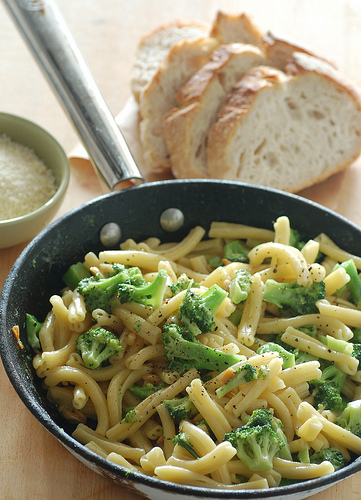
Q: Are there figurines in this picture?
A: No, there are no figurines.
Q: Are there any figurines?
A: No, there are no figurines.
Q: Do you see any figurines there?
A: No, there are no figurines.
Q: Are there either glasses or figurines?
A: No, there are no figurines or glasses.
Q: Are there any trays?
A: No, there are no trays.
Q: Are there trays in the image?
A: No, there are no trays.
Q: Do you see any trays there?
A: No, there are no trays.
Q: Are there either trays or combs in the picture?
A: No, there are no trays or combs.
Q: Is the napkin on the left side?
A: Yes, the napkin is on the left of the image.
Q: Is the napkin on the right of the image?
A: No, the napkin is on the left of the image.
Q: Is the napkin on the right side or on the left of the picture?
A: The napkin is on the left of the image.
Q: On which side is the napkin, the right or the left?
A: The napkin is on the left of the image.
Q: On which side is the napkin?
A: The napkin is on the left of the image.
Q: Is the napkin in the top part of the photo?
A: Yes, the napkin is in the top of the image.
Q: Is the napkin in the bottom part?
A: No, the napkin is in the top of the image.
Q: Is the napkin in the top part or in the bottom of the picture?
A: The napkin is in the top of the image.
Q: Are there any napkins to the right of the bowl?
A: Yes, there is a napkin to the right of the bowl.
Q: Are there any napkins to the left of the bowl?
A: No, the napkin is to the right of the bowl.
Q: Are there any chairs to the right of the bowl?
A: No, there is a napkin to the right of the bowl.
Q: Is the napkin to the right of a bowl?
A: Yes, the napkin is to the right of a bowl.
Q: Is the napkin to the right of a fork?
A: No, the napkin is to the right of a bowl.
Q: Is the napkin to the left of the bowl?
A: No, the napkin is to the right of the bowl.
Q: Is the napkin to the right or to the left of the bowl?
A: The napkin is to the right of the bowl.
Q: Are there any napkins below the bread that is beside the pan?
A: Yes, there is a napkin below the bread.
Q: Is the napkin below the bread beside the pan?
A: Yes, the napkin is below the bread.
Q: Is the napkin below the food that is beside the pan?
A: Yes, the napkin is below the bread.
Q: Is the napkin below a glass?
A: No, the napkin is below the bread.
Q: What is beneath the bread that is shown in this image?
A: The napkin is beneath the bread.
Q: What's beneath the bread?
A: The napkin is beneath the bread.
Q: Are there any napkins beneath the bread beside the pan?
A: Yes, there is a napkin beneath the bread.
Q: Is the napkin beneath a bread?
A: Yes, the napkin is beneath a bread.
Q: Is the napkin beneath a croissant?
A: No, the napkin is beneath a bread.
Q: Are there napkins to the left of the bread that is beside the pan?
A: Yes, there is a napkin to the left of the bread.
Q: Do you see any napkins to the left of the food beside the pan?
A: Yes, there is a napkin to the left of the bread.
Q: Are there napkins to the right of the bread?
A: No, the napkin is to the left of the bread.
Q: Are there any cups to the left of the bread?
A: No, there is a napkin to the left of the bread.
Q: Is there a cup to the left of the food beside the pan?
A: No, there is a napkin to the left of the bread.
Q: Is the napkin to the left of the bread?
A: Yes, the napkin is to the left of the bread.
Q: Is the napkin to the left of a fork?
A: No, the napkin is to the left of the bread.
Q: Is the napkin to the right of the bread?
A: No, the napkin is to the left of the bread.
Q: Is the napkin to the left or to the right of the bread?
A: The napkin is to the left of the bread.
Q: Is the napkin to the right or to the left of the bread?
A: The napkin is to the left of the bread.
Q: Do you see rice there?
A: Yes, there is rice.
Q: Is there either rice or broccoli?
A: Yes, there is rice.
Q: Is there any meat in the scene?
A: No, there is no meat.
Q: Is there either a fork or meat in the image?
A: No, there are no meat or forks.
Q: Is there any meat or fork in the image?
A: No, there are no meat or forks.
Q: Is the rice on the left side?
A: Yes, the rice is on the left of the image.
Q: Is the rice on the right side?
A: No, the rice is on the left of the image.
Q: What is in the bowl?
A: The rice is in the bowl.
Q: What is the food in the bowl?
A: The food is rice.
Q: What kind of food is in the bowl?
A: The food is rice.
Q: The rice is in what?
A: The rice is in the bowl.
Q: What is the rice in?
A: The rice is in the bowl.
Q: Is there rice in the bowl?
A: Yes, there is rice in the bowl.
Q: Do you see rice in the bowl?
A: Yes, there is rice in the bowl.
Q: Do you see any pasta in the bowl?
A: No, there is rice in the bowl.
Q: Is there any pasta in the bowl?
A: No, there is rice in the bowl.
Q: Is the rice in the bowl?
A: Yes, the rice is in the bowl.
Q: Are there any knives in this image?
A: No, there are no knives.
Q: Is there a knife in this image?
A: No, there are no knives.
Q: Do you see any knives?
A: No, there are no knives.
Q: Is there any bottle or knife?
A: No, there are no knives or bottles.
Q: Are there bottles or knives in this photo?
A: No, there are no knives or bottles.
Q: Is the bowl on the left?
A: Yes, the bowl is on the left of the image.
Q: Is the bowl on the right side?
A: No, the bowl is on the left of the image.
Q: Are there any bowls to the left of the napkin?
A: Yes, there is a bowl to the left of the napkin.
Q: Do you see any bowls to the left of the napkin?
A: Yes, there is a bowl to the left of the napkin.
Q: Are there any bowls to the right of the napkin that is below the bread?
A: No, the bowl is to the left of the napkin.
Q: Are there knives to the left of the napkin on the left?
A: No, there is a bowl to the left of the napkin.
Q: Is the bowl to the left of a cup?
A: No, the bowl is to the left of the napkin.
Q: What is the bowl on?
A: The bowl is on the counter.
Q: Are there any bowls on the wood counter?
A: Yes, there is a bowl on the counter.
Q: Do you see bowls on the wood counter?
A: Yes, there is a bowl on the counter.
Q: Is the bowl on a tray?
A: No, the bowl is on the counter.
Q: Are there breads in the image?
A: Yes, there is a bread.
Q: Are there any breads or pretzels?
A: Yes, there is a bread.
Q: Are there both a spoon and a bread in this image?
A: No, there is a bread but no spoons.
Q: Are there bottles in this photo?
A: No, there are no bottles.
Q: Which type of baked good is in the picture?
A: The baked good is a bread.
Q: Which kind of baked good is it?
A: The food is a bread.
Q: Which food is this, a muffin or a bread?
A: This is a bread.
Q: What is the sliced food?
A: The food is a bread.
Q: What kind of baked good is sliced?
A: The baked good is a bread.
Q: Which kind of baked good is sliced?
A: The baked good is a bread.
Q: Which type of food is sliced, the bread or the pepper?
A: The bread is sliced.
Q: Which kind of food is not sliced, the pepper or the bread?
A: The pepper is not sliced.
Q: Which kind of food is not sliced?
A: The food is a pepper.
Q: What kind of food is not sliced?
A: The food is a pepper.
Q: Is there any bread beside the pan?
A: Yes, there is a bread beside the pan.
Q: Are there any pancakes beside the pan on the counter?
A: No, there is a bread beside the pan.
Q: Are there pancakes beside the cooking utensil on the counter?
A: No, there is a bread beside the pan.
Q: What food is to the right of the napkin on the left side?
A: The food is a bread.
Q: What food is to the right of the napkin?
A: The food is a bread.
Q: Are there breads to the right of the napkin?
A: Yes, there is a bread to the right of the napkin.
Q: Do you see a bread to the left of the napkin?
A: No, the bread is to the right of the napkin.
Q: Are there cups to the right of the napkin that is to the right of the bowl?
A: No, there is a bread to the right of the napkin.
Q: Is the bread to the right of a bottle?
A: No, the bread is to the right of a napkin.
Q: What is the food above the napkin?
A: The food is a bread.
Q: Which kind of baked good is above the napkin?
A: The food is a bread.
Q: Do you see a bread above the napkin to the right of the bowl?
A: Yes, there is a bread above the napkin.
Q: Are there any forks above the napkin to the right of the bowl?
A: No, there is a bread above the napkin.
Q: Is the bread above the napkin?
A: Yes, the bread is above the napkin.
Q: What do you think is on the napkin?
A: The bread is on the napkin.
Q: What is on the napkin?
A: The bread is on the napkin.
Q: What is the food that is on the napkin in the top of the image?
A: The food is a bread.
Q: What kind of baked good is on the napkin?
A: The food is a bread.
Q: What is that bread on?
A: The bread is on the napkin.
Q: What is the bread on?
A: The bread is on the napkin.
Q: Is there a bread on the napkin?
A: Yes, there is a bread on the napkin.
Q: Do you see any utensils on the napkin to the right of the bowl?
A: No, there is a bread on the napkin.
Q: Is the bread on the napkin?
A: Yes, the bread is on the napkin.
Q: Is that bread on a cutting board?
A: No, the bread is on the napkin.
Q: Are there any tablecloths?
A: No, there are no tablecloths.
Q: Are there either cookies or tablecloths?
A: No, there are no tablecloths or cookies.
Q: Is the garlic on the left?
A: Yes, the garlic is on the left of the image.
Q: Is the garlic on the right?
A: No, the garlic is on the left of the image.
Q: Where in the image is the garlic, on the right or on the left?
A: The garlic is on the left of the image.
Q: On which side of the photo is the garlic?
A: The garlic is on the left of the image.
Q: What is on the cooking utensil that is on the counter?
A: The garlic is on the pan.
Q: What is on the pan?
A: The garlic is on the pan.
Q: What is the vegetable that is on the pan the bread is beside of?
A: The vegetable is garlic.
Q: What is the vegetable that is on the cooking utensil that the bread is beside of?
A: The vegetable is garlic.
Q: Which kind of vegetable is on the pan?
A: The vegetable is garlic.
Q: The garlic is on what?
A: The garlic is on the pan.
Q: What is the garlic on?
A: The garlic is on the pan.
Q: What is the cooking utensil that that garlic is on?
A: The cooking utensil is a pan.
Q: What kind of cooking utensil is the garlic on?
A: The garlic is on the pan.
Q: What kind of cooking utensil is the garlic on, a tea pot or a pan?
A: The garlic is on a pan.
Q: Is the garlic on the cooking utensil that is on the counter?
A: Yes, the garlic is on the pan.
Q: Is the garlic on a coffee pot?
A: No, the garlic is on the pan.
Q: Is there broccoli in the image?
A: Yes, there is broccoli.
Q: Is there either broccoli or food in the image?
A: Yes, there is broccoli.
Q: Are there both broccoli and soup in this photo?
A: No, there is broccoli but no soup.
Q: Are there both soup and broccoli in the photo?
A: No, there is broccoli but no soup.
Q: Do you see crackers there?
A: No, there are no crackers.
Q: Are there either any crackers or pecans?
A: No, there are no crackers or pecans.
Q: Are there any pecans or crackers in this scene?
A: No, there are no crackers or pecans.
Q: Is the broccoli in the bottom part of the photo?
A: Yes, the broccoli is in the bottom of the image.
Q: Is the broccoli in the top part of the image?
A: No, the broccoli is in the bottom of the image.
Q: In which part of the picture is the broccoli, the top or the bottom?
A: The broccoli is in the bottom of the image.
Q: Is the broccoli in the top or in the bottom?
A: The broccoli is in the bottom of the image.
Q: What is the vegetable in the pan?
A: The vegetable is broccoli.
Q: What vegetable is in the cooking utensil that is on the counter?
A: The vegetable is broccoli.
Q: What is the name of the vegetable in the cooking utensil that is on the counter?
A: The vegetable is broccoli.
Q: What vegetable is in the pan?
A: The vegetable is broccoli.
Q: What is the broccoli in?
A: The broccoli is in the pan.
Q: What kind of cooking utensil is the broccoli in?
A: The broccoli is in the pan.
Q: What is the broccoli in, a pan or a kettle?
A: The broccoli is in a pan.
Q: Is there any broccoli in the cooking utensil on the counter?
A: Yes, there is broccoli in the pan.